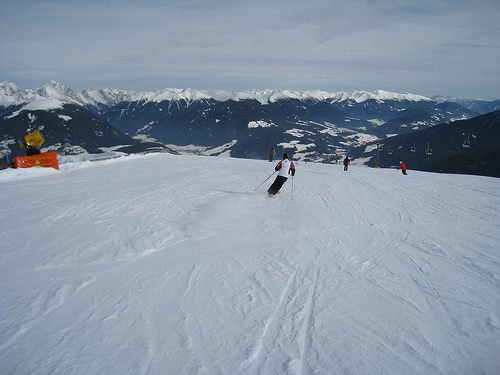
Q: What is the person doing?
A: Skiing.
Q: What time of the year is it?
A: Winter.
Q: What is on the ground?
A: Snow.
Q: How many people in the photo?
A: 3.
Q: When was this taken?
A: Evening.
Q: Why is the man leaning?
A: To keep from falling off the skis.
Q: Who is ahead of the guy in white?
A: 2 other skiers.